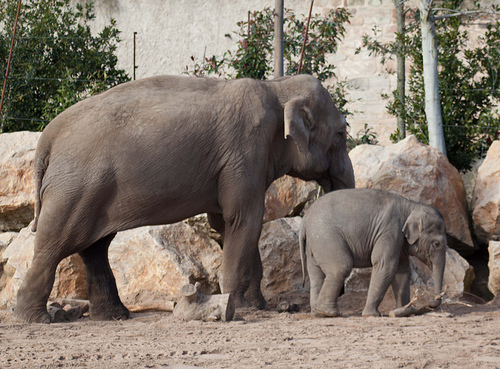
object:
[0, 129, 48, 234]
stone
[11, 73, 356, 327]
elephants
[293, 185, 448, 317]
elephant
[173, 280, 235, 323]
log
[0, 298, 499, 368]
ground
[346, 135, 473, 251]
rock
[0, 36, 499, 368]
enclosure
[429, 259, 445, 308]
trunk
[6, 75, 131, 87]
wires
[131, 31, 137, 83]
pole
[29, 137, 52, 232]
tail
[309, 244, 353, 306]
legs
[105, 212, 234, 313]
boulders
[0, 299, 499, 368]
dirt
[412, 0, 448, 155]
tree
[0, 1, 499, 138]
wall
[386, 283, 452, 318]
branch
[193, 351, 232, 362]
marks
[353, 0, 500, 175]
bush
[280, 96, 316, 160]
ears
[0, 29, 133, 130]
fence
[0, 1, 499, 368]
scene